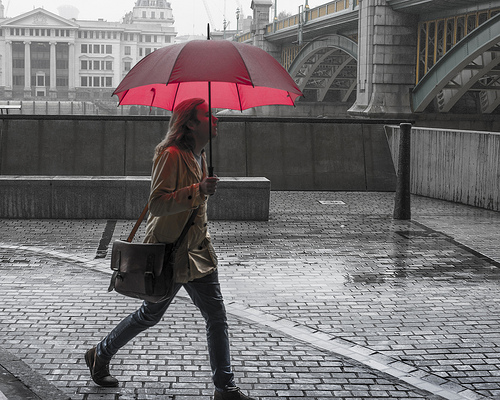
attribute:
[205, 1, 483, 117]
bridge — metal, stone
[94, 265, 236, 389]
pants — brown, leather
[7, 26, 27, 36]
detail — very white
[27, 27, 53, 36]
detail — very white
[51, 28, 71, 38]
detail — very white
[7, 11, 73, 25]
detail — very white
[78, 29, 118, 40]
detail — very white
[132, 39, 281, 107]
red umbrella — open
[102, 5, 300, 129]
umbrella — red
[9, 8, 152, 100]
building — white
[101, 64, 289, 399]
man — light skinned